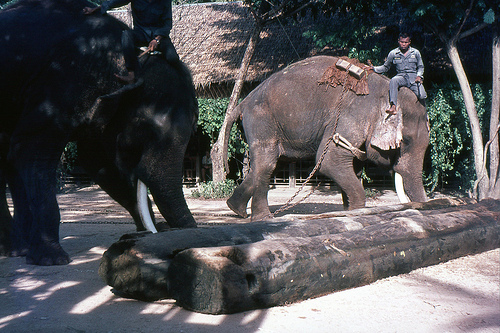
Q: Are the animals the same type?
A: Yes, all the animals are elephants.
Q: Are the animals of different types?
A: No, all the animals are elephants.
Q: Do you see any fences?
A: No, there are no fences.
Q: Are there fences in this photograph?
A: No, there are no fences.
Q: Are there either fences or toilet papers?
A: No, there are no fences or toilet papers.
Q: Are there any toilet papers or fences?
A: No, there are no fences or toilet papers.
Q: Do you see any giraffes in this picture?
A: No, there are no giraffes.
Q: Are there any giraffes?
A: No, there are no giraffes.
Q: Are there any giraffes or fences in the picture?
A: No, there are no giraffes or fences.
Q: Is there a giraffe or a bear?
A: No, there are no giraffes or bears.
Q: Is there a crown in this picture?
A: No, there are no crowns.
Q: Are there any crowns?
A: No, there are no crowns.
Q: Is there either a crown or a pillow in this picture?
A: No, there are no crowns or pillows.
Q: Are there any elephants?
A: Yes, there is an elephant.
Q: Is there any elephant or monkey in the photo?
A: Yes, there is an elephant.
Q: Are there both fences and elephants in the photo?
A: No, there is an elephant but no fences.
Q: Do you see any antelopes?
A: No, there are no antelopes.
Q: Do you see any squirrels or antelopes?
A: No, there are no antelopes or squirrels.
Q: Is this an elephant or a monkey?
A: This is an elephant.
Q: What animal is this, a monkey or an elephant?
A: This is an elephant.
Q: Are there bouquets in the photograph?
A: No, there are no bouquets.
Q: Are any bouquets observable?
A: No, there are no bouquets.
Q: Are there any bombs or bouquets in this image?
A: No, there are no bouquets or bombs.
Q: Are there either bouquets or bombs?
A: No, there are no bouquets or bombs.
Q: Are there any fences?
A: No, there are no fences.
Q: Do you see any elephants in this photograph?
A: Yes, there is an elephant.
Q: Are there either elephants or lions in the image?
A: Yes, there is an elephant.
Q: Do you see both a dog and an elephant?
A: No, there is an elephant but no dogs.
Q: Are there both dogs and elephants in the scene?
A: No, there is an elephant but no dogs.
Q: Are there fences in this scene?
A: No, there are no fences.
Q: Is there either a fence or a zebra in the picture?
A: No, there are no fences or zebras.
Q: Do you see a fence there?
A: No, there are no fences.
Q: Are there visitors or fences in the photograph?
A: No, there are no fences or visitors.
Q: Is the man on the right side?
A: Yes, the man is on the right of the image.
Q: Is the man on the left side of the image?
A: No, the man is on the right of the image.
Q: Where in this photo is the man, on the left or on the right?
A: The man is on the right of the image.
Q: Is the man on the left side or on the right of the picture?
A: The man is on the right of the image.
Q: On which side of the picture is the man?
A: The man is on the right of the image.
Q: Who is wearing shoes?
A: The man is wearing shoes.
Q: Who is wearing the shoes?
A: The man is wearing shoes.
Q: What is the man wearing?
A: The man is wearing shoes.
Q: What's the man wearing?
A: The man is wearing shoes.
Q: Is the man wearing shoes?
A: Yes, the man is wearing shoes.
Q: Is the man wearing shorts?
A: No, the man is wearing shoes.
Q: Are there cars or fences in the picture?
A: No, there are no fences or cars.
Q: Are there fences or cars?
A: No, there are no fences or cars.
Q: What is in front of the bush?
A: The tree is in front of the bush.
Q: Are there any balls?
A: No, there are no balls.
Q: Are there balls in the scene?
A: No, there are no balls.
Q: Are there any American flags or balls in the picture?
A: No, there are no balls or American flags.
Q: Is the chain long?
A: Yes, the chain is long.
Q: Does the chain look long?
A: Yes, the chain is long.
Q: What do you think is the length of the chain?
A: The chain is long.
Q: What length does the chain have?
A: The chain has long length.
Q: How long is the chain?
A: The chain is long.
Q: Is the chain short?
A: No, the chain is long.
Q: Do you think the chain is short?
A: No, the chain is long.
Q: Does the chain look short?
A: No, the chain is long.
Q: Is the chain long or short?
A: The chain is long.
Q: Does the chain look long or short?
A: The chain is long.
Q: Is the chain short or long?
A: The chain is long.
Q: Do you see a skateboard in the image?
A: No, there are no skateboards.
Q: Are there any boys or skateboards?
A: No, there are no skateboards or boys.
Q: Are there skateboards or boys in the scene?
A: No, there are no skateboards or boys.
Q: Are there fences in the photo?
A: No, there are no fences.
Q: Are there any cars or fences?
A: No, there are no fences or cars.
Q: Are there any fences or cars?
A: No, there are no fences or cars.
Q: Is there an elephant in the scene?
A: Yes, there is an elephant.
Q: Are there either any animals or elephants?
A: Yes, there is an elephant.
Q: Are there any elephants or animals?
A: Yes, there is an elephant.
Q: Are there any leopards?
A: No, there are no leopards.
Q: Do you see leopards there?
A: No, there are no leopards.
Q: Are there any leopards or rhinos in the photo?
A: No, there are no leopards or rhinos.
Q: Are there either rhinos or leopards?
A: No, there are no leopards or rhinos.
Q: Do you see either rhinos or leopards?
A: No, there are no leopards or rhinos.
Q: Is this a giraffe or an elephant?
A: This is an elephant.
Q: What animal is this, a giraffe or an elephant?
A: This is an elephant.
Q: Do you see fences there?
A: No, there are no fences.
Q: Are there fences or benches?
A: No, there are no fences or benches.